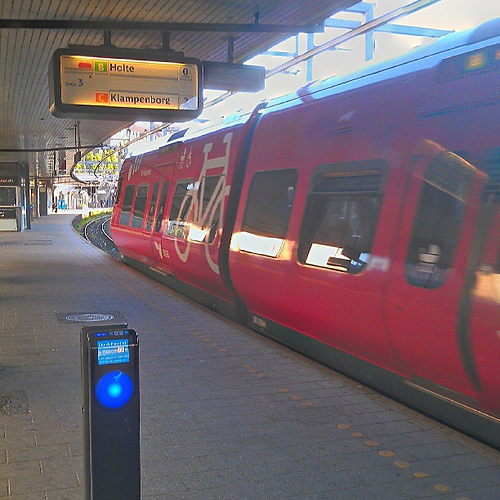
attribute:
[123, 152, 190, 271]
train door — closed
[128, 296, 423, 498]
platform — paved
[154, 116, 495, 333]
train — red